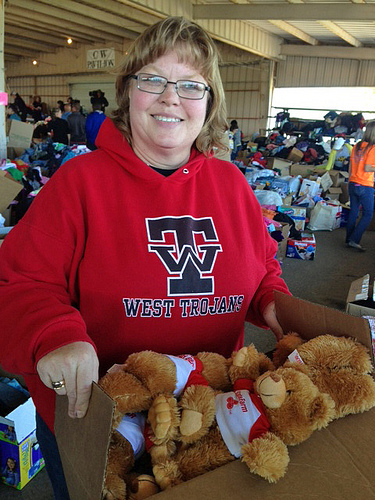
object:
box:
[52, 287, 374, 499]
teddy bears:
[96, 350, 229, 423]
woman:
[0, 17, 293, 499]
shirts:
[213, 378, 271, 460]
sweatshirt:
[0, 114, 292, 436]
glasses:
[130, 72, 213, 101]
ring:
[49, 380, 66, 390]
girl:
[345, 120, 374, 253]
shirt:
[347, 140, 374, 185]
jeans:
[346, 180, 374, 243]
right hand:
[37, 341, 99, 417]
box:
[344, 272, 374, 345]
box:
[0, 376, 46, 492]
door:
[276, 56, 374, 88]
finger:
[49, 365, 67, 394]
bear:
[148, 365, 337, 489]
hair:
[111, 16, 230, 158]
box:
[287, 234, 317, 261]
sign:
[84, 46, 114, 69]